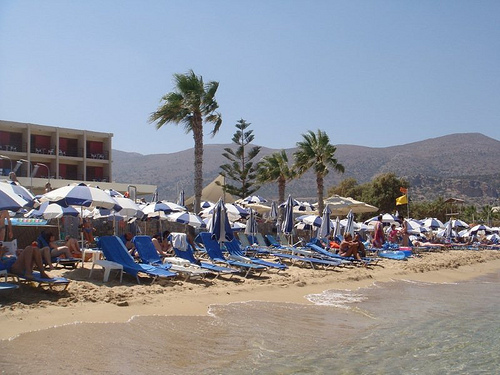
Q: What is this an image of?
A: The beach.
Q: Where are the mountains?
A: To the right.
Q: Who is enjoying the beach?
A: Tourists.